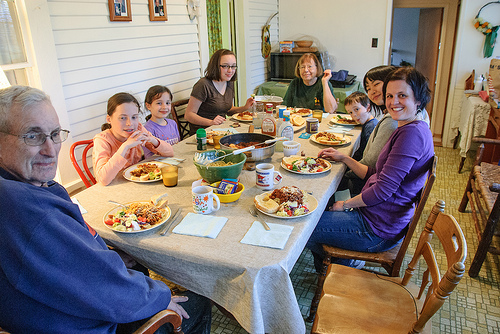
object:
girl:
[140, 85, 181, 160]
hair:
[145, 83, 174, 122]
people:
[89, 45, 437, 274]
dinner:
[254, 185, 310, 217]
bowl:
[218, 132, 276, 159]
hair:
[0, 86, 49, 131]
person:
[344, 91, 381, 162]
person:
[85, 88, 180, 186]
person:
[184, 48, 257, 136]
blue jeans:
[306, 205, 407, 269]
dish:
[102, 197, 169, 233]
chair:
[310, 199, 469, 334]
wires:
[365, 268, 418, 324]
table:
[60, 100, 365, 275]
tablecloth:
[55, 104, 379, 329]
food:
[282, 154, 327, 173]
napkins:
[240, 220, 294, 249]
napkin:
[172, 212, 229, 239]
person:
[304, 68, 435, 274]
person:
[336, 64, 431, 196]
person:
[281, 53, 338, 115]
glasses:
[0, 129, 70, 147]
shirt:
[359, 119, 436, 242]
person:
[91, 92, 174, 186]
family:
[0, 38, 436, 334]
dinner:
[129, 163, 168, 180]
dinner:
[314, 131, 347, 145]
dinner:
[237, 110, 257, 120]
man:
[0, 85, 215, 334]